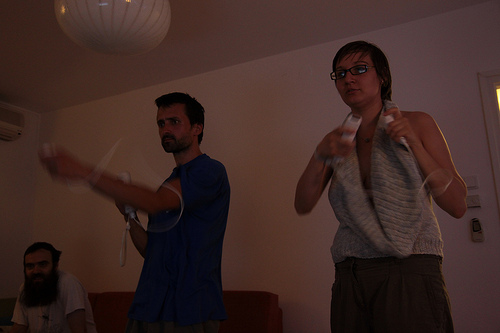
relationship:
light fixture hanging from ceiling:
[52, 4, 173, 61] [5, 0, 493, 111]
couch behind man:
[3, 287, 289, 331] [36, 91, 238, 329]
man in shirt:
[36, 91, 238, 329] [128, 152, 230, 325]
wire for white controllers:
[411, 168, 456, 204] [382, 115, 407, 148]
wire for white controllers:
[411, 168, 456, 204] [339, 114, 364, 147]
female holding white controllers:
[289, 37, 469, 332] [339, 114, 364, 147]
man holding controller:
[140, 93, 231, 328] [35, 141, 60, 160]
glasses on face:
[328, 64, 382, 81] [332, 54, 372, 108]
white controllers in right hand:
[339, 114, 364, 147] [315, 129, 354, 158]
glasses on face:
[329, 64, 381, 84] [337, 53, 384, 106]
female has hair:
[289, 37, 466, 332] [332, 40, 393, 108]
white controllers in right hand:
[339, 114, 364, 147] [322, 129, 353, 158]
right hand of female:
[322, 129, 353, 158] [289, 37, 469, 332]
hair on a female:
[332, 40, 392, 96] [289, 37, 469, 332]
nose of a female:
[345, 71, 357, 85] [289, 37, 469, 332]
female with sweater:
[289, 37, 469, 332] [328, 100, 445, 260]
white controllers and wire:
[379, 112, 412, 156] [432, 176, 455, 199]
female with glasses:
[289, 37, 469, 332] [329, 63, 381, 81]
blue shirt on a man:
[127, 155, 232, 319] [36, 91, 238, 329]